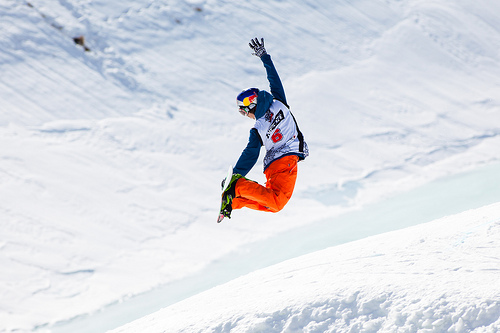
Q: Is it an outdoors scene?
A: Yes, it is outdoors.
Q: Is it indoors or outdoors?
A: It is outdoors.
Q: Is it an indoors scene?
A: No, it is outdoors.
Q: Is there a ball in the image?
A: No, there are no balls.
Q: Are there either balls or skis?
A: No, there are no balls or skis.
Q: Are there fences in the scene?
A: No, there are no fences.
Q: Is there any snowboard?
A: Yes, there is a snowboard.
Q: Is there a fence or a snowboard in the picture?
A: Yes, there is a snowboard.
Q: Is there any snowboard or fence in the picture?
A: Yes, there is a snowboard.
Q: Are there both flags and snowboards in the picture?
A: No, there is a snowboard but no flags.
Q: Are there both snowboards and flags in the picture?
A: No, there is a snowboard but no flags.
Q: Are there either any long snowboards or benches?
A: Yes, there is a long snowboard.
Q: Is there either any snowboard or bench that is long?
A: Yes, the snowboard is long.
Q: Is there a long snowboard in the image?
A: Yes, there is a long snowboard.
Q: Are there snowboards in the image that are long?
A: Yes, there is a snowboard that is long.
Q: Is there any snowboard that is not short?
A: Yes, there is a long snowboard.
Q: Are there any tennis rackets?
A: No, there are no tennis rackets.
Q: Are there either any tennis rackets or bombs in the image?
A: No, there are no tennis rackets or bombs.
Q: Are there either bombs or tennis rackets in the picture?
A: No, there are no tennis rackets or bombs.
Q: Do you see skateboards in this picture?
A: No, there are no skateboards.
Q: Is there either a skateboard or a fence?
A: No, there are no skateboards or fences.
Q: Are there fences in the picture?
A: No, there are no fences.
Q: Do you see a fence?
A: No, there are no fences.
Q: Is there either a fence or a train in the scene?
A: No, there are no fences or trains.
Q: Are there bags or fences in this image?
A: No, there are no bags or fences.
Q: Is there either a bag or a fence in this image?
A: No, there are no bags or fences.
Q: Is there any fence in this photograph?
A: No, there are no fences.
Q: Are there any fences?
A: No, there are no fences.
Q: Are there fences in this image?
A: No, there are no fences.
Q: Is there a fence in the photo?
A: No, there are no fences.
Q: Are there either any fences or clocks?
A: No, there are no fences or clocks.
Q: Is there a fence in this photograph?
A: No, there are no fences.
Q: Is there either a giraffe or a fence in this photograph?
A: No, there are no fences or giraffes.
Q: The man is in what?
A: The man is in the air.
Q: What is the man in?
A: The man is in the air.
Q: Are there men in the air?
A: Yes, there is a man in the air.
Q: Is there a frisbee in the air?
A: No, there is a man in the air.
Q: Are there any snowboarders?
A: Yes, there is a snowboarder.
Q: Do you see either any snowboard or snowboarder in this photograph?
A: Yes, there is a snowboarder.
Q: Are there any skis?
A: No, there are no skis.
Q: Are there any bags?
A: No, there are no bags.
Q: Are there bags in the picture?
A: No, there are no bags.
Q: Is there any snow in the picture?
A: Yes, there is snow.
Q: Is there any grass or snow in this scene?
A: Yes, there is snow.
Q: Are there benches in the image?
A: No, there are no benches.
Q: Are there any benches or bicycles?
A: No, there are no benches or bicycles.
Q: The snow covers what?
A: The snow covers the mountain.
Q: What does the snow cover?
A: The snow covers the mountain.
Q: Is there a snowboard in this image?
A: Yes, there is a snowboard.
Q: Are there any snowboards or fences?
A: Yes, there is a snowboard.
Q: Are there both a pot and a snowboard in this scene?
A: No, there is a snowboard but no pots.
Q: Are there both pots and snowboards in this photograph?
A: No, there is a snowboard but no pots.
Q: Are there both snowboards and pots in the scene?
A: No, there is a snowboard but no pots.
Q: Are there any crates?
A: No, there are no crates.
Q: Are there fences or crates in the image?
A: No, there are no crates or fences.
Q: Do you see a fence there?
A: No, there are no fences.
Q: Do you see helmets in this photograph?
A: Yes, there is a helmet.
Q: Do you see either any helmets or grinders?
A: Yes, there is a helmet.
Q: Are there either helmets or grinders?
A: Yes, there is a helmet.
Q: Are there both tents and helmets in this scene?
A: No, there is a helmet but no tents.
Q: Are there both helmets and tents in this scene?
A: No, there is a helmet but no tents.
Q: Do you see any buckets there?
A: No, there are no buckets.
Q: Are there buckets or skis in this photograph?
A: No, there are no buckets or skis.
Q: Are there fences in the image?
A: No, there are no fences.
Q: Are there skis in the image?
A: No, there are no skis.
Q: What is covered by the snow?
A: The mountain is covered by the snow.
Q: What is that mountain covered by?
A: The mountain is covered by the snow.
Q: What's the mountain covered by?
A: The mountain is covered by the snow.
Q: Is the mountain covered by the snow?
A: Yes, the mountain is covered by the snow.